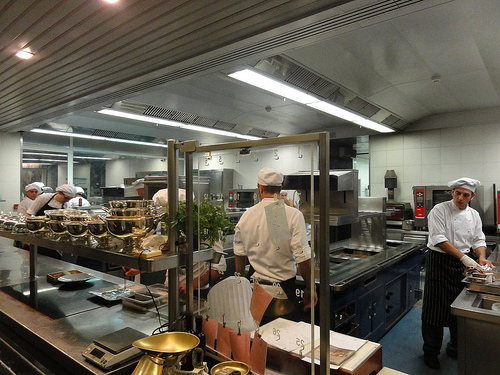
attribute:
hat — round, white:
[447, 178, 479, 192]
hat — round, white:
[256, 171, 286, 190]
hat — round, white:
[24, 183, 38, 190]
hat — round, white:
[56, 184, 78, 198]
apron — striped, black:
[420, 250, 475, 326]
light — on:
[228, 68, 393, 135]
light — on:
[97, 107, 265, 142]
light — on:
[30, 128, 168, 149]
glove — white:
[461, 257, 484, 274]